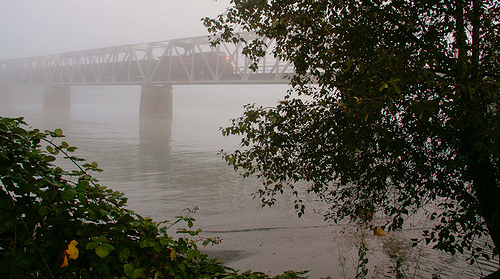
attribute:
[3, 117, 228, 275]
bush — wet , green leaved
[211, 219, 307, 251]
bank — river 